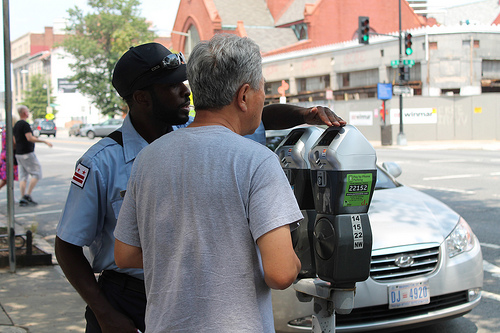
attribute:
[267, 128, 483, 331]
car — silver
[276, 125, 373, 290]
meter — grey, silver, modern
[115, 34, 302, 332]
man — standing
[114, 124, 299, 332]
tshirt — grey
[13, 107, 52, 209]
man — bald, standing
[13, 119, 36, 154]
shirt — black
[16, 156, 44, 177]
shorts — khaki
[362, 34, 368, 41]
light — green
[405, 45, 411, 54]
light — green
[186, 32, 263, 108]
hair — gray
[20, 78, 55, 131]
tree — green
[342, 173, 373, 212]
sticker — green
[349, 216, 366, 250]
sticker — white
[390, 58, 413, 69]
sign — green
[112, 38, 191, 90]
hat — black